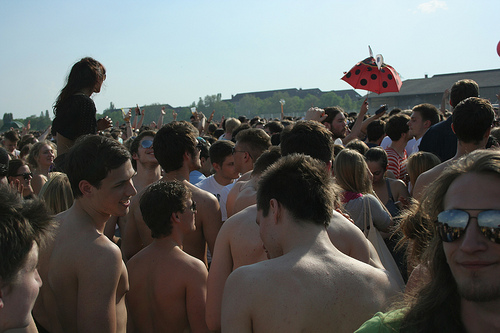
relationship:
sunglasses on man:
[435, 207, 499, 249] [354, 146, 499, 329]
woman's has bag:
[325, 139, 397, 231] [320, 148, 388, 198]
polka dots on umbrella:
[353, 69, 380, 88] [343, 50, 404, 102]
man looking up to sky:
[104, 130, 166, 263] [6, 4, 490, 106]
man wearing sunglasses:
[332, 157, 496, 327] [430, 207, 498, 242]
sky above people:
[0, 0, 499, 120] [1, 57, 499, 332]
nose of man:
[460, 216, 490, 283] [350, 148, 500, 333]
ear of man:
[169, 206, 188, 230] [120, 176, 211, 331]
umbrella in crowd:
[338, 47, 486, 95] [0, 92, 500, 331]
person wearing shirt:
[379, 108, 415, 187] [383, 144, 413, 185]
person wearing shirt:
[44, 41, 113, 153] [46, 89, 100, 142]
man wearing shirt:
[192, 140, 241, 269] [193, 173, 243, 262]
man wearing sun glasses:
[104, 127, 166, 255] [131, 124, 173, 163]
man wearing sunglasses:
[350, 148, 500, 333] [430, 198, 485, 242]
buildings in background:
[100, 70, 497, 108] [0, 70, 495, 117]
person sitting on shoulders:
[50, 57, 113, 171] [40, 139, 96, 180]